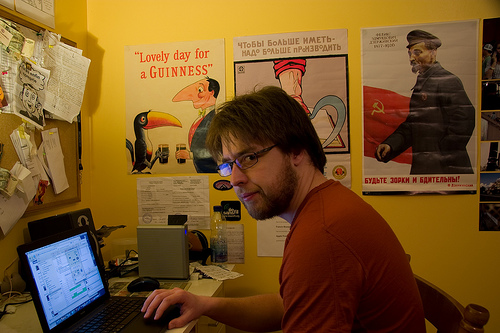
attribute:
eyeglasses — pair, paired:
[215, 155, 256, 172]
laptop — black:
[24, 235, 160, 329]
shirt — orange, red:
[276, 182, 404, 327]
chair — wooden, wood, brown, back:
[402, 285, 475, 324]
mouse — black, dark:
[129, 279, 148, 291]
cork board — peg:
[51, 123, 90, 160]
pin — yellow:
[42, 41, 55, 52]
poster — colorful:
[354, 29, 470, 197]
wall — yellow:
[134, 0, 176, 20]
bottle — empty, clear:
[210, 211, 227, 268]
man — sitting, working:
[191, 84, 393, 324]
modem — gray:
[134, 226, 182, 281]